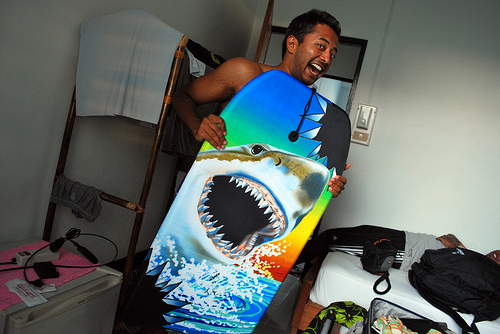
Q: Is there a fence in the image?
A: No, there are no fences.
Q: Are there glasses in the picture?
A: No, there are no glasses.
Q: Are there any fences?
A: No, there are no fences.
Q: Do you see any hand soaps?
A: No, there are no hand soaps.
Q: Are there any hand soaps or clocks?
A: No, there are no hand soaps or clocks.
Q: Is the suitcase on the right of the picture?
A: Yes, the suitcase is on the right of the image.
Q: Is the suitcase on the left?
A: No, the suitcase is on the right of the image.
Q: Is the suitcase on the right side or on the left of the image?
A: The suitcase is on the right of the image.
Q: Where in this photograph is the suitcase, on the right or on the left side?
A: The suitcase is on the right of the image.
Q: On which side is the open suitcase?
A: The suitcase is on the right of the image.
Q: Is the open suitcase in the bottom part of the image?
A: Yes, the suitcase is in the bottom of the image.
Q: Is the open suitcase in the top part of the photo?
A: No, the suitcase is in the bottom of the image.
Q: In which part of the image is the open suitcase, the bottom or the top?
A: The suitcase is in the bottom of the image.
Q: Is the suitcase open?
A: Yes, the suitcase is open.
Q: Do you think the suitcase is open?
A: Yes, the suitcase is open.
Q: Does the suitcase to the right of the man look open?
A: Yes, the suitcase is open.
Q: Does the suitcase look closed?
A: No, the suitcase is open.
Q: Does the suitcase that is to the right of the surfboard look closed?
A: No, the suitcase is open.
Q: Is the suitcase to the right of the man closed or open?
A: The suitcase is open.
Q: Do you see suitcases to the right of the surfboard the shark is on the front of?
A: Yes, there is a suitcase to the right of the surfboard.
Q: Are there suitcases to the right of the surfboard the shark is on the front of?
A: Yes, there is a suitcase to the right of the surfboard.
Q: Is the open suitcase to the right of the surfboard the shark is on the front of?
A: Yes, the suitcase is to the right of the surfboard.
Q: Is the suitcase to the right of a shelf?
A: No, the suitcase is to the right of the surfboard.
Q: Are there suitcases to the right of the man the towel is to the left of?
A: Yes, there is a suitcase to the right of the man.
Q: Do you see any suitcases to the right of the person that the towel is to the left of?
A: Yes, there is a suitcase to the right of the man.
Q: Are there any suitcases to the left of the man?
A: No, the suitcase is to the right of the man.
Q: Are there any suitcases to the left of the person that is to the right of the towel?
A: No, the suitcase is to the right of the man.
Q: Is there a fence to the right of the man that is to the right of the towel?
A: No, there is a suitcase to the right of the man.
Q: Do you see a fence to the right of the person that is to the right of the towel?
A: No, there is a suitcase to the right of the man.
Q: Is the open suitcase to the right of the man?
A: Yes, the suitcase is to the right of the man.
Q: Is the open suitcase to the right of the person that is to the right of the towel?
A: Yes, the suitcase is to the right of the man.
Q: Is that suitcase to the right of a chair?
A: No, the suitcase is to the right of the man.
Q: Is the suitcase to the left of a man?
A: No, the suitcase is to the right of a man.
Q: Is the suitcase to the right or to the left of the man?
A: The suitcase is to the right of the man.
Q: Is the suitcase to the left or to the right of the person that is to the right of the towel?
A: The suitcase is to the right of the man.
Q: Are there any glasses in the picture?
A: No, there are no glasses.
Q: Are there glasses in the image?
A: No, there are no glasses.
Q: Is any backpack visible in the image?
A: Yes, there is a backpack.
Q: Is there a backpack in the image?
A: Yes, there is a backpack.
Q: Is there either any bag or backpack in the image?
A: Yes, there is a backpack.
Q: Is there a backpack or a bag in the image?
A: Yes, there is a backpack.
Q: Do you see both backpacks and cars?
A: No, there is a backpack but no cars.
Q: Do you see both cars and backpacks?
A: No, there is a backpack but no cars.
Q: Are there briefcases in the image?
A: No, there are no briefcases.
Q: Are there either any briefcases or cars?
A: No, there are no briefcases or cars.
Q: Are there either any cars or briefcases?
A: No, there are no briefcases or cars.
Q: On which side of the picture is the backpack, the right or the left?
A: The backpack is on the right of the image.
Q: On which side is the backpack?
A: The backpack is on the right of the image.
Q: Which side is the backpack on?
A: The backpack is on the right of the image.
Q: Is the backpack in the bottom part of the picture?
A: Yes, the backpack is in the bottom of the image.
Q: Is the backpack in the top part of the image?
A: No, the backpack is in the bottom of the image.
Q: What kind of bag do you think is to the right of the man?
A: The bag is a backpack.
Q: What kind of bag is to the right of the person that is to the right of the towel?
A: The bag is a backpack.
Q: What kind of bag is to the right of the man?
A: The bag is a backpack.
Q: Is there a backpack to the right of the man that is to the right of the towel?
A: Yes, there is a backpack to the right of the man.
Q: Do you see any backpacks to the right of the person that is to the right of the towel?
A: Yes, there is a backpack to the right of the man.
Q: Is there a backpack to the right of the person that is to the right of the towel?
A: Yes, there is a backpack to the right of the man.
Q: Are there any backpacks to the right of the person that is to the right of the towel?
A: Yes, there is a backpack to the right of the man.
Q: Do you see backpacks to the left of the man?
A: No, the backpack is to the right of the man.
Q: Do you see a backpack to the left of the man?
A: No, the backpack is to the right of the man.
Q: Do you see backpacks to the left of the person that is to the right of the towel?
A: No, the backpack is to the right of the man.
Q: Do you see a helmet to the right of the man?
A: No, there is a backpack to the right of the man.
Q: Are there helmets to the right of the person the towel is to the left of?
A: No, there is a backpack to the right of the man.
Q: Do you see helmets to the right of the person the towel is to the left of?
A: No, there is a backpack to the right of the man.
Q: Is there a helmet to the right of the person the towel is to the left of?
A: No, there is a backpack to the right of the man.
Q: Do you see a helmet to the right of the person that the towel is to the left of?
A: No, there is a backpack to the right of the man.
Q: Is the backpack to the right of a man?
A: Yes, the backpack is to the right of a man.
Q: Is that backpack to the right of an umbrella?
A: No, the backpack is to the right of a man.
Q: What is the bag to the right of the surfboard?
A: The bag is a backpack.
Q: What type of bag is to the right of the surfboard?
A: The bag is a backpack.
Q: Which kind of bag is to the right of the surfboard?
A: The bag is a backpack.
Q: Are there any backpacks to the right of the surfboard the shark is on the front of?
A: Yes, there is a backpack to the right of the surfboard.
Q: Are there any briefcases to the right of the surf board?
A: No, there is a backpack to the right of the surf board.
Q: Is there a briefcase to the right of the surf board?
A: No, there is a backpack to the right of the surf board.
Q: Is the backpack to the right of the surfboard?
A: Yes, the backpack is to the right of the surfboard.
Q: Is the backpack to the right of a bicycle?
A: No, the backpack is to the right of the surfboard.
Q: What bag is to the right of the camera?
A: The bag is a backpack.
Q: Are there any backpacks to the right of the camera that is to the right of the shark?
A: Yes, there is a backpack to the right of the camera.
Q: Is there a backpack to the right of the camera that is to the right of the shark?
A: Yes, there is a backpack to the right of the camera.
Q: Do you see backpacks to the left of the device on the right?
A: No, the backpack is to the right of the camera.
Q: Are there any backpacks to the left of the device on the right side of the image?
A: No, the backpack is to the right of the camera.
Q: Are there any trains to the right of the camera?
A: No, there is a backpack to the right of the camera.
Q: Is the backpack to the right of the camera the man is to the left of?
A: Yes, the backpack is to the right of the camera.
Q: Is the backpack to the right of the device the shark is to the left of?
A: Yes, the backpack is to the right of the camera.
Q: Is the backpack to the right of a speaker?
A: No, the backpack is to the right of the camera.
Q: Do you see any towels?
A: Yes, there is a towel.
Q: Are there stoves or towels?
A: Yes, there is a towel.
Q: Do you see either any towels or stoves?
A: Yes, there is a towel.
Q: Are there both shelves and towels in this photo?
A: No, there is a towel but no shelves.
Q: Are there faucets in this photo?
A: No, there are no faucets.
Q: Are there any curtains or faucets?
A: No, there are no faucets or curtains.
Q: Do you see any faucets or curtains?
A: No, there are no faucets or curtains.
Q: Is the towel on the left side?
A: Yes, the towel is on the left of the image.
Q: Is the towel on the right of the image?
A: No, the towel is on the left of the image.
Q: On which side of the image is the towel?
A: The towel is on the left of the image.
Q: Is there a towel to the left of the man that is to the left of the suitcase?
A: Yes, there is a towel to the left of the man.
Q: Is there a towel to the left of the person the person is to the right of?
A: Yes, there is a towel to the left of the man.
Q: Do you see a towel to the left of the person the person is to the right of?
A: Yes, there is a towel to the left of the man.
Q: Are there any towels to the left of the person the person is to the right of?
A: Yes, there is a towel to the left of the man.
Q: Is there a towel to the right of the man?
A: No, the towel is to the left of the man.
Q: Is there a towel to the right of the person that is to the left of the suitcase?
A: No, the towel is to the left of the man.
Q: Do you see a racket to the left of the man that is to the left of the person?
A: No, there is a towel to the left of the man.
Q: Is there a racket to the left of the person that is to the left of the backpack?
A: No, there is a towel to the left of the man.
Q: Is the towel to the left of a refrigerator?
A: No, the towel is to the left of a man.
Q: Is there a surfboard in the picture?
A: Yes, there is a surfboard.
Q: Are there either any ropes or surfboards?
A: Yes, there is a surfboard.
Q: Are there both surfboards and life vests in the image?
A: No, there is a surfboard but no life jackets.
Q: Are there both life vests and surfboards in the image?
A: No, there is a surfboard but no life jackets.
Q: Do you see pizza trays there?
A: No, there are no pizza trays.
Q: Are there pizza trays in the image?
A: No, there are no pizza trays.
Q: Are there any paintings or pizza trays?
A: No, there are no pizza trays or paintings.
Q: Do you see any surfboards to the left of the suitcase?
A: Yes, there is a surfboard to the left of the suitcase.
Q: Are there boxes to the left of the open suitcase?
A: No, there is a surfboard to the left of the suitcase.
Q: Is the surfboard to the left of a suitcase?
A: Yes, the surfboard is to the left of a suitcase.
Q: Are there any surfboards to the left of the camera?
A: Yes, there is a surfboard to the left of the camera.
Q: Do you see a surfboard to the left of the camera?
A: Yes, there is a surfboard to the left of the camera.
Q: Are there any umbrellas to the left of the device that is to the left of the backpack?
A: No, there is a surfboard to the left of the camera.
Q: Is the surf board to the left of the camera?
A: Yes, the surf board is to the left of the camera.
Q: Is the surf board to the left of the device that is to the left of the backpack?
A: Yes, the surf board is to the left of the camera.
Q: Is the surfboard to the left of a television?
A: No, the surfboard is to the left of the camera.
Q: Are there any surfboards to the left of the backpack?
A: Yes, there is a surfboard to the left of the backpack.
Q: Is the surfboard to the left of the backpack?
A: Yes, the surfboard is to the left of the backpack.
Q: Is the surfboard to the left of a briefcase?
A: No, the surfboard is to the left of the backpack.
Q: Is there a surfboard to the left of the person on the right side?
A: Yes, there is a surfboard to the left of the person.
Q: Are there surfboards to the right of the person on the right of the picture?
A: No, the surfboard is to the left of the person.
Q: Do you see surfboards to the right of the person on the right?
A: No, the surfboard is to the left of the person.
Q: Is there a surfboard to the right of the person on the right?
A: No, the surfboard is to the left of the person.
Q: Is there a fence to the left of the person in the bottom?
A: No, there is a surfboard to the left of the person.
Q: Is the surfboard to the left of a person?
A: Yes, the surfboard is to the left of a person.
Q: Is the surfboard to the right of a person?
A: No, the surfboard is to the left of a person.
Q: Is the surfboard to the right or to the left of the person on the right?
A: The surfboard is to the left of the person.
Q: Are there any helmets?
A: No, there are no helmets.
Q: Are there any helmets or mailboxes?
A: No, there are no helmets or mailboxes.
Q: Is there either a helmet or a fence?
A: No, there are no fences or helmets.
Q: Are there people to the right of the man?
A: Yes, there is a person to the right of the man.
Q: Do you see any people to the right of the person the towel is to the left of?
A: Yes, there is a person to the right of the man.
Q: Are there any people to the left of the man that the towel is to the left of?
A: No, the person is to the right of the man.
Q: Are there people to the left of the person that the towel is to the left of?
A: No, the person is to the right of the man.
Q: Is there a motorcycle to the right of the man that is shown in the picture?
A: No, there is a person to the right of the man.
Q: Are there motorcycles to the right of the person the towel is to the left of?
A: No, there is a person to the right of the man.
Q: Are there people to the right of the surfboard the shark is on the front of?
A: Yes, there is a person to the right of the surfboard.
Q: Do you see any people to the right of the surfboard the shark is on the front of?
A: Yes, there is a person to the right of the surfboard.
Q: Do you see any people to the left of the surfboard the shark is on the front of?
A: No, the person is to the right of the surfboard.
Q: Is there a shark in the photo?
A: Yes, there is a shark.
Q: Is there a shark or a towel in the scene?
A: Yes, there is a shark.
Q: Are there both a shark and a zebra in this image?
A: No, there is a shark but no zebras.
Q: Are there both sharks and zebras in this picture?
A: No, there is a shark but no zebras.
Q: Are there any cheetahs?
A: No, there are no cheetahs.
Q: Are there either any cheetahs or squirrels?
A: No, there are no cheetahs or squirrels.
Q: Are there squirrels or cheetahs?
A: No, there are no cheetahs or squirrels.